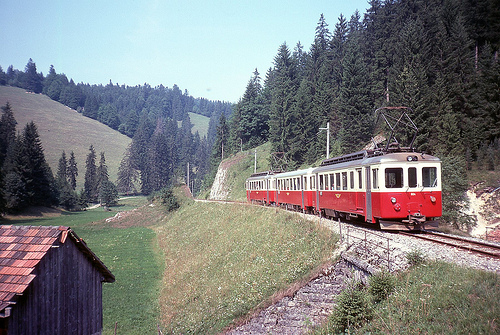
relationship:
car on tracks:
[244, 150, 442, 231] [415, 223, 484, 255]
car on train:
[238, 148, 442, 236] [234, 140, 446, 221]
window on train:
[385, 168, 404, 188] [242, 138, 448, 224]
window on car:
[422, 167, 437, 187] [244, 150, 442, 231]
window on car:
[382, 165, 440, 185] [244, 150, 442, 231]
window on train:
[407, 167, 417, 189] [237, 148, 449, 229]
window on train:
[381, 159, 441, 189] [245, 157, 446, 235]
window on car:
[385, 168, 404, 188] [244, 150, 442, 231]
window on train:
[383, 165, 439, 194] [237, 148, 449, 229]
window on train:
[382, 165, 440, 185] [234, 137, 450, 229]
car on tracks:
[244, 150, 442, 231] [405, 224, 483, 249]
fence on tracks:
[345, 226, 391, 270] [410, 220, 484, 256]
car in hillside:
[244, 150, 442, 231] [4, 57, 219, 221]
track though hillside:
[194, 192, 483, 258] [4, 57, 219, 221]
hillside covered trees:
[4, 60, 219, 185] [215, 15, 475, 144]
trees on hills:
[230, 63, 410, 165] [180, 98, 387, 316]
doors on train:
[358, 163, 376, 207] [255, 122, 496, 240]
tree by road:
[93, 179, 121, 208] [81, 199, 100, 212]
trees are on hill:
[18, 60, 160, 132] [7, 102, 121, 188]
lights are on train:
[384, 197, 439, 206] [252, 147, 442, 219]